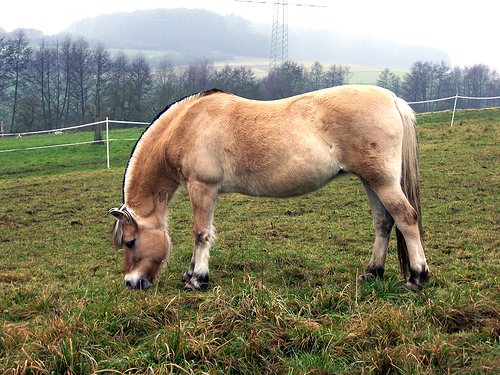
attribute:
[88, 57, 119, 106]
tree — leafless, tall, dark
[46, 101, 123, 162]
line — white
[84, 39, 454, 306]
horse — grazing, large, strong, eating, brown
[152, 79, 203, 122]
mane — black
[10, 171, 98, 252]
grass — green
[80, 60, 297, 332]
pony — white, lending, brown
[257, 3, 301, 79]
object — tall, cellphone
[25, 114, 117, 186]
fence — white, up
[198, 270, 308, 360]
wisp — multi-colored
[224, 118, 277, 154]
fur — brown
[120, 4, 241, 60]
cloud — gray